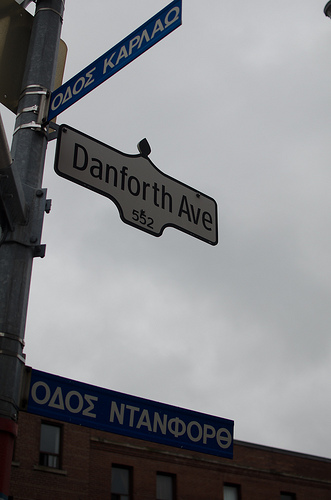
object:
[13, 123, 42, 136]
clasp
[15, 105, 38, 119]
clasp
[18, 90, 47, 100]
clasp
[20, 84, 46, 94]
clasp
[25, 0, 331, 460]
cloud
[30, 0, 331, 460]
sky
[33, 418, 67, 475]
balcony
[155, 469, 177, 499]
window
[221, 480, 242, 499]
window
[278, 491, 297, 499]
window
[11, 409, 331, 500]
building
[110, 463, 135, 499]
window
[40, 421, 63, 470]
window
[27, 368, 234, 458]
foreign language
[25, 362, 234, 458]
sign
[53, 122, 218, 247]
sign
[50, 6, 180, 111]
letters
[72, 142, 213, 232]
letters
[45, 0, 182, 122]
blue sign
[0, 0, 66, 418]
pole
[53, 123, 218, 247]
elephants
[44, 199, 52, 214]
bolt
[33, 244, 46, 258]
bolt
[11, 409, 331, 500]
wall